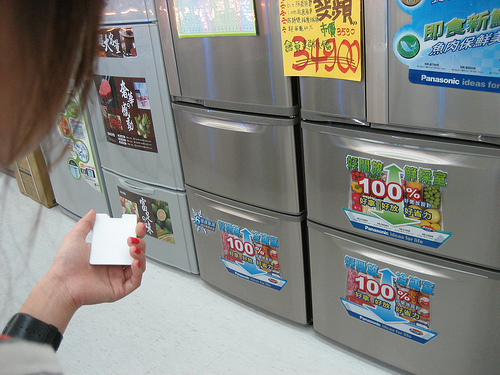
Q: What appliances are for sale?
A: Refrigerators.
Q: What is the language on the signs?
A: Chinese.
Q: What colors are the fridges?
A: Stainless or grey.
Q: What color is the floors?
A: White tiled.